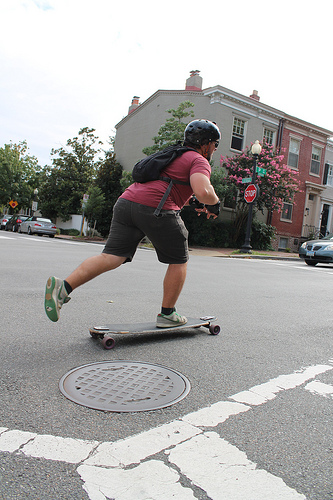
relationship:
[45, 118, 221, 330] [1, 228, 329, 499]
skateboarder in middle of road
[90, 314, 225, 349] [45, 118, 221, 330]
skateboard under skateboarder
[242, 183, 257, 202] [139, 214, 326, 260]
stop sign at corner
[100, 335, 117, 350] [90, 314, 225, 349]
wheel on skateboard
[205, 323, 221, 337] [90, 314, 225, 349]
wheel on skateboard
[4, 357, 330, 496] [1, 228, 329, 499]
lines on road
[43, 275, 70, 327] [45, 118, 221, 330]
shoe on skateboarder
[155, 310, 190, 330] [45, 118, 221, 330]
shoe on skateboarder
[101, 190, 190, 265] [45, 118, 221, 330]
shorts on skateboarder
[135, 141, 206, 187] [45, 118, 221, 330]
backpack on skateboarder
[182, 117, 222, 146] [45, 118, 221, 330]
helmet on skateboarder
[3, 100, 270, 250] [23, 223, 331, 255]
trees along sidewalk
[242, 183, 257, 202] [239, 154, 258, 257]
stop sign on light pole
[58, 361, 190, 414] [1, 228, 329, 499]
manhole on road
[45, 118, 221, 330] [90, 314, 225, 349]
skateboarder on skateboard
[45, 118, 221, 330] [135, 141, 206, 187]
skateboarder has backpack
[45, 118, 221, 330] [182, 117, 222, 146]
skateboarder wearing helmet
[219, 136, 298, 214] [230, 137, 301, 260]
flowers on tree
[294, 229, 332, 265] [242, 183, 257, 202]
car at stop sign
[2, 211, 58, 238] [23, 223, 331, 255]
cars by sidewalk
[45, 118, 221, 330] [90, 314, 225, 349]
skateboarder riding skateboard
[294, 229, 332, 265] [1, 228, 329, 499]
car driving on road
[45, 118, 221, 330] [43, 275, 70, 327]
skateboarder wearing shoe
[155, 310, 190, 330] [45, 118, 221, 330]
shoe of skateboarder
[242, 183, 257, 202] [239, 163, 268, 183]
stop sign next to street signs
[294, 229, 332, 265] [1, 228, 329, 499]
car parked on road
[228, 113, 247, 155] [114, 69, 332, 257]
window of building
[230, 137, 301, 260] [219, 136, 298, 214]
tree has flowers